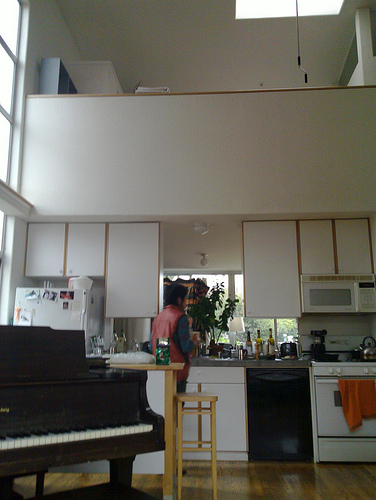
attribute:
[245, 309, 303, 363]
window — kitchen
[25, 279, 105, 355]
door — top, room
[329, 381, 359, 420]
towel — orange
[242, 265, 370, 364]
microwave — oven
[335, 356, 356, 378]
knob — white, cabinet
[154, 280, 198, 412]
person — standing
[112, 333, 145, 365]
switch — part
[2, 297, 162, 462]
piano — set, black, keys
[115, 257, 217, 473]
man — wearing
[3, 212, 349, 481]
kitchen — white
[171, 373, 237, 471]
stool — wood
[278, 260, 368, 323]
top — white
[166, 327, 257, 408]
package — green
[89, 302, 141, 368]
glass — three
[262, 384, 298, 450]
dish — black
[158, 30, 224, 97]
ceiling — white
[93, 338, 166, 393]
counter — next